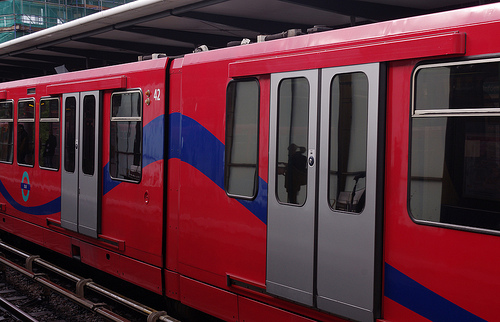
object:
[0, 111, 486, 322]
stripe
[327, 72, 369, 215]
window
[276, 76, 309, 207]
window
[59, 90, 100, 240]
door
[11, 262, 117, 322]
rocks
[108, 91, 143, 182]
window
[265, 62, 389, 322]
door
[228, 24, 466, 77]
bar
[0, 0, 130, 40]
guard rail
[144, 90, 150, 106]
lights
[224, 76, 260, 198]
window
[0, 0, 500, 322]
rail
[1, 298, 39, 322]
metal track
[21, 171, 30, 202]
logo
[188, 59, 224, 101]
red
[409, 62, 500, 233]
window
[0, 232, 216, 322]
tracks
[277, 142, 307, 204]
reflection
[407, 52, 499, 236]
window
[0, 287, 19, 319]
rust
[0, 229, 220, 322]
railroad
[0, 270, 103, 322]
ground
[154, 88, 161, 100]
number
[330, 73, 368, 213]
reflection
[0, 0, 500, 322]
car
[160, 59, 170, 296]
division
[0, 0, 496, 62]
canopy